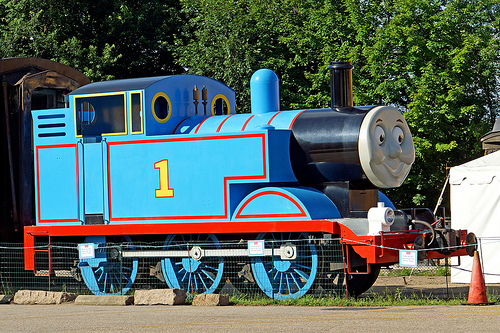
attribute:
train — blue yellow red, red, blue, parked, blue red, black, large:
[30, 53, 486, 307]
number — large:
[150, 155, 177, 202]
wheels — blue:
[70, 235, 330, 303]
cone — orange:
[451, 246, 495, 309]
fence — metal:
[2, 232, 500, 306]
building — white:
[437, 142, 499, 285]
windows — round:
[149, 81, 232, 129]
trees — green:
[1, 1, 499, 240]